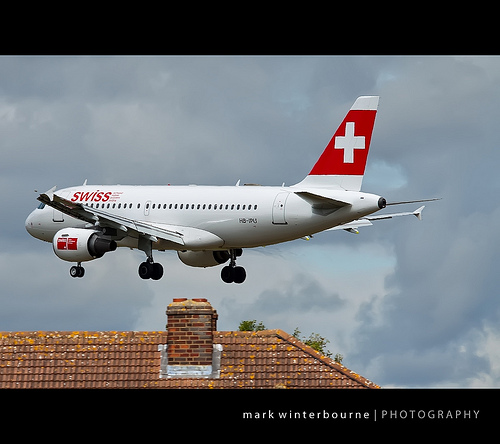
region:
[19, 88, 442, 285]
The plane in the air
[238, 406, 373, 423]
The name of the photographer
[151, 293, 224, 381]
The chimney on the roof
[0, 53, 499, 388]
The clouds in the sky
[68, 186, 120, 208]
The red writing on the plane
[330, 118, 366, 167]
The white cross on the plane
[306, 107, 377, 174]
The red part of the tail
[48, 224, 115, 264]
The left engine of the plane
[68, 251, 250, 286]
The landing gear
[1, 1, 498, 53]
The black stripe on the top of the photo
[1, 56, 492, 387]
Swiss Airlines plane flying over a house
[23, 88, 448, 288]
Swiss airlines plane flying low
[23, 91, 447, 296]
plane with landing gear down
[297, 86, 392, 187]
Swiss airlines logo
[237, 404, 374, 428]
Mark Winterbourne logo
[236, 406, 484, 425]
Mark Winterbourne Photography logo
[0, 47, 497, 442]
Mark Winterbourne Photography picture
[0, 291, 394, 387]
red brick roofing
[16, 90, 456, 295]
Swiss Airlines plane in the sky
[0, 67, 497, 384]
flying over a neighborhood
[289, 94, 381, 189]
The back wing of a gray airplane with a red on it.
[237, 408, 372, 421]
The name mark winterbourne on the bottom of the photograph.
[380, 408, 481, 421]
The word PHOTOGRAPHY.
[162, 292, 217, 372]
Chimney on the side of the roof.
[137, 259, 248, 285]
Black wheels on both sides of the plane.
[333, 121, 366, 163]
Gray colored cross on the tail end of the wing.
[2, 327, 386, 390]
Brown and orange colored roof.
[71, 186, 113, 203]
The word SWISS on the side of a plane.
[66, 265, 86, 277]
Front two black wheels on an airplane.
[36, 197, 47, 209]
Front windshield of a plane.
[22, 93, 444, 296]
an airplane flying away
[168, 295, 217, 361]
the chimney on the house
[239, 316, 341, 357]
the tree behind the house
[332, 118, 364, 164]
the logo on the back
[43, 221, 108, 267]
the engine on the lane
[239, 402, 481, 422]
the writing in the corner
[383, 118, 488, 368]
a big cloud on the side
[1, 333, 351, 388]
the roof of the house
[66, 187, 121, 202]
the name of the airline on the plane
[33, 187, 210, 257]
the wing of the plane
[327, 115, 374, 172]
white cross on the plane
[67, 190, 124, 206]
red logo on the plane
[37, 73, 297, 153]
grey clouds in the sky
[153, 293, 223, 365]
brick chimney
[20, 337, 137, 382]
red tiles on the roof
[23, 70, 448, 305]
red and white airplane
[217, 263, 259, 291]
wheel of the plane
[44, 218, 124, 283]
engine of the plane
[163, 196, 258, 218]
windows on the plane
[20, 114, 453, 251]
the plane is flying low